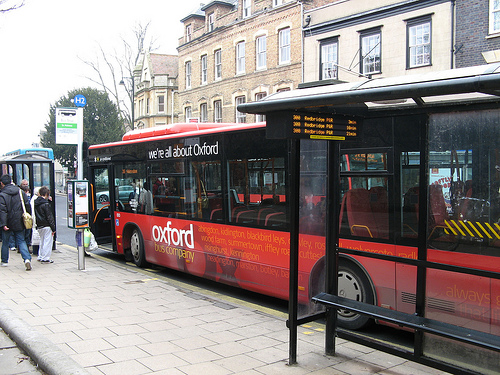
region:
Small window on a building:
[181, 57, 195, 97]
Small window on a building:
[195, 48, 211, 90]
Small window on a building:
[210, 46, 226, 83]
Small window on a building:
[231, 37, 246, 82]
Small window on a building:
[249, 28, 268, 69]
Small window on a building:
[270, 24, 299, 70]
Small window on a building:
[310, 36, 341, 81]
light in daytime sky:
[0, 0, 205, 150]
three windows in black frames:
[316, 12, 433, 82]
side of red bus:
[88, 102, 498, 354]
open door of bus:
[87, 163, 113, 253]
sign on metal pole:
[55, 106, 83, 268]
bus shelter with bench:
[242, 64, 496, 372]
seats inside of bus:
[207, 198, 284, 223]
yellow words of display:
[290, 112, 356, 135]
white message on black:
[146, 138, 219, 160]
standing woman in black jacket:
[33, 186, 55, 263]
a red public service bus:
[83, 108, 498, 355]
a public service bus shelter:
[236, 60, 497, 371]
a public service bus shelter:
[2, 152, 57, 248]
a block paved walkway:
[3, 235, 450, 374]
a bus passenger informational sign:
[53, 106, 77, 145]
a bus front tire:
[124, 226, 143, 266]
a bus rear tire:
[317, 263, 372, 329]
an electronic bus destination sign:
[111, 164, 142, 176]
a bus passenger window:
[147, 158, 189, 216]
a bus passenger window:
[186, 160, 226, 222]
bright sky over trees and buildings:
[3, 4, 193, 149]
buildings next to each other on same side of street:
[126, 3, 497, 128]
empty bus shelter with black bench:
[238, 64, 494, 372]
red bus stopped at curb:
[83, 72, 494, 368]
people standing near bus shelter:
[1, 147, 59, 272]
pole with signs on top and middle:
[56, 90, 90, 272]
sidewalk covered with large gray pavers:
[3, 220, 450, 370]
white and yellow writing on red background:
[147, 217, 195, 263]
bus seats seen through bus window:
[225, 155, 288, 232]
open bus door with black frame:
[83, 152, 120, 258]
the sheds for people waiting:
[1, 60, 499, 365]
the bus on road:
[0, 116, 499, 358]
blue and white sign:
[73, 91, 85, 106]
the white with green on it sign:
[53, 103, 80, 149]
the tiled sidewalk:
[1, 240, 486, 372]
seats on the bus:
[151, 185, 474, 236]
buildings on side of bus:
[130, 0, 496, 130]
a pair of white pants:
[34, 226, 54, 263]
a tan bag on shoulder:
[18, 184, 33, 224]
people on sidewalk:
[0, 170, 97, 272]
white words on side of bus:
[147, 217, 196, 247]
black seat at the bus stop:
[310, 280, 411, 321]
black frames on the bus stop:
[276, 252, 316, 353]